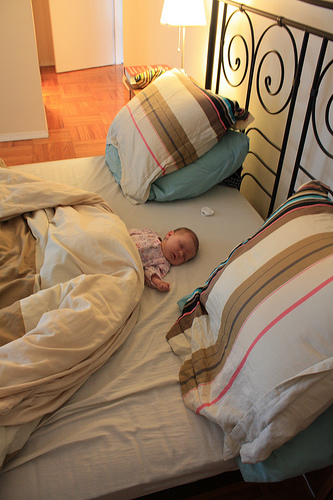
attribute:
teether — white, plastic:
[202, 206, 216, 216]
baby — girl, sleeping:
[122, 220, 206, 296]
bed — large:
[2, 0, 332, 477]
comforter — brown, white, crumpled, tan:
[1, 167, 142, 466]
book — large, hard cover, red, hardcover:
[118, 62, 171, 87]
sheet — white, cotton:
[6, 161, 275, 477]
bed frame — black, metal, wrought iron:
[200, 0, 332, 219]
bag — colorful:
[133, 68, 167, 86]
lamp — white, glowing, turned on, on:
[159, 0, 211, 68]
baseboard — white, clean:
[1, 127, 54, 147]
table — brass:
[120, 63, 181, 105]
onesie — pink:
[125, 226, 170, 282]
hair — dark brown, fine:
[173, 224, 213, 256]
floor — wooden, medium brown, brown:
[2, 66, 142, 166]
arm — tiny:
[149, 270, 170, 294]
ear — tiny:
[163, 228, 177, 241]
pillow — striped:
[91, 64, 254, 202]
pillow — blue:
[103, 135, 257, 206]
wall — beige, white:
[1, 1, 53, 144]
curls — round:
[217, 6, 304, 114]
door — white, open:
[48, 1, 118, 72]